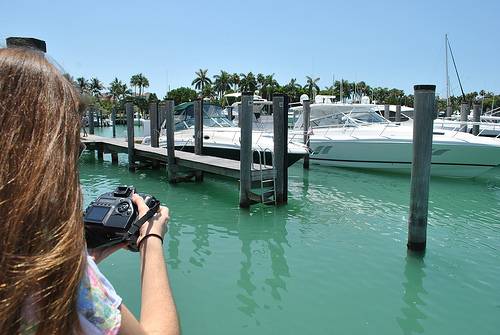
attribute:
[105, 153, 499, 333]
water — green-blue, murky, turquoise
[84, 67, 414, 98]
palm trees — tall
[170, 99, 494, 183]
boats — docked, white, nice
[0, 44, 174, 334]
woman — photographer, white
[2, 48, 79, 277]
hair — brown, thick, shoulder length, shining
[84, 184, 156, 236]
camera — digital, black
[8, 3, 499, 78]
sky — pale blue, clear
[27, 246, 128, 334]
shirt — short sleeved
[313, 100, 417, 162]
boat — white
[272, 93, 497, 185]
boat — sleek, white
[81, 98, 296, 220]
dock — wooden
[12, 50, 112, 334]
hair — photographers 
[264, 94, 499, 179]
boat — white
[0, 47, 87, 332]
hair — long, brown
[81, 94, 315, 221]
pier — wooden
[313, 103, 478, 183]
boat — sleek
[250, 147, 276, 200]
ladder — metal